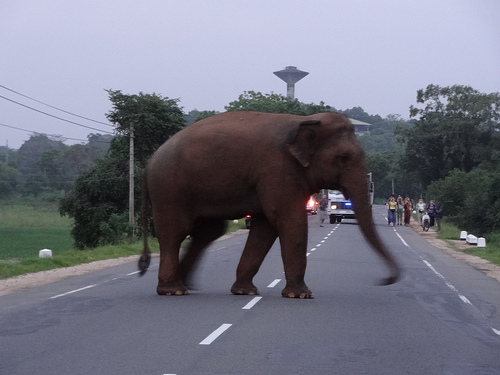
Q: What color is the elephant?
A: Gray and brown.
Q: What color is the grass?
A: Green.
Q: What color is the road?
A: Gray.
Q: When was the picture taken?
A: Daytime.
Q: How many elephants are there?
A: One.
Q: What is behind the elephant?
A: A truck.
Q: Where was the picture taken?
A: On the street.